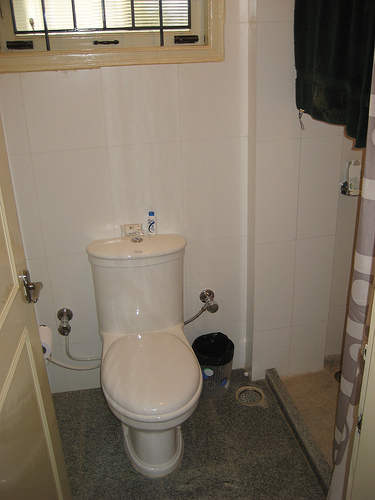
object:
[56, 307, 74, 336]
plumbing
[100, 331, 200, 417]
lid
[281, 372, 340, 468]
floor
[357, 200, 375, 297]
part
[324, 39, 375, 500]
curtain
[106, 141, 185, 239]
tiles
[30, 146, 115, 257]
tiles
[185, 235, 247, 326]
tiles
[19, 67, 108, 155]
tiles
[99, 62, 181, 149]
tiles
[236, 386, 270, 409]
drain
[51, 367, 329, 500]
floor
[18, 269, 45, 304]
handle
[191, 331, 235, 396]
trashcan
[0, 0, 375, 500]
bathroom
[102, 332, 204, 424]
toilet seat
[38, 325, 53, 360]
toilet paper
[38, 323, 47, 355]
holder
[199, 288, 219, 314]
plumbing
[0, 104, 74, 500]
door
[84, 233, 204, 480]
toilet